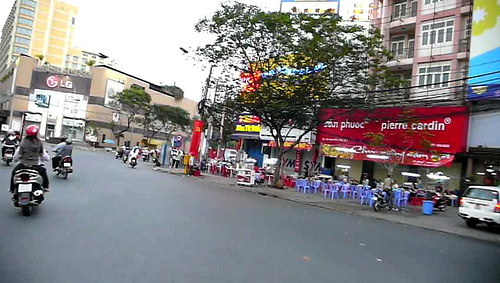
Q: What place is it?
A: It is a road.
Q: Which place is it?
A: It is a road.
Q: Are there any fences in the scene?
A: No, there are no fences.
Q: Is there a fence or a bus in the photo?
A: No, there are no fences or buses.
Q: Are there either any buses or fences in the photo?
A: No, there are no fences or buses.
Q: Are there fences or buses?
A: No, there are no fences or buses.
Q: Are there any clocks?
A: No, there are no clocks.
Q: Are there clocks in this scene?
A: No, there are no clocks.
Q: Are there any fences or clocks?
A: No, there are no clocks or fences.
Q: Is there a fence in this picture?
A: No, there are no fences.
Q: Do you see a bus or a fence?
A: No, there are no fences or buses.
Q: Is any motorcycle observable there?
A: Yes, there is a motorcycle.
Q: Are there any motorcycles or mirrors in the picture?
A: Yes, there is a motorcycle.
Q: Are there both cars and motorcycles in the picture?
A: Yes, there are both a motorcycle and a car.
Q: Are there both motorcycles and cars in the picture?
A: Yes, there are both a motorcycle and a car.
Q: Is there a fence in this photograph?
A: No, there are no fences.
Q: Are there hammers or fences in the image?
A: No, there are no fences or hammers.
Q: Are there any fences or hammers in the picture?
A: No, there are no fences or hammers.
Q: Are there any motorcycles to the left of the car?
A: Yes, there is a motorcycle to the left of the car.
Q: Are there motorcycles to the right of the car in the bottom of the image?
A: No, the motorcycle is to the left of the car.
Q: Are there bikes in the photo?
A: Yes, there is a bike.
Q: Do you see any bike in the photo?
A: Yes, there is a bike.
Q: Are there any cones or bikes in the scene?
A: Yes, there is a bike.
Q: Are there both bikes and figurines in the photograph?
A: No, there is a bike but no figurines.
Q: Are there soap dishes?
A: No, there are no soap dishes.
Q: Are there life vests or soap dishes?
A: No, there are no soap dishes or life vests.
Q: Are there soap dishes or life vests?
A: No, there are no soap dishes or life vests.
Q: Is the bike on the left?
A: Yes, the bike is on the left of the image.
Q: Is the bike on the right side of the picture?
A: No, the bike is on the left of the image.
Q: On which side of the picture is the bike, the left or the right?
A: The bike is on the left of the image.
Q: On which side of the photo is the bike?
A: The bike is on the left of the image.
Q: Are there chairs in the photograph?
A: Yes, there is a chair.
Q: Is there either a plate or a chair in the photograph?
A: Yes, there is a chair.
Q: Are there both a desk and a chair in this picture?
A: No, there is a chair but no desks.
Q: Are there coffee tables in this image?
A: No, there are no coffee tables.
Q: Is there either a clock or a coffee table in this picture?
A: No, there are no coffee tables or clocks.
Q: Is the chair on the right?
A: Yes, the chair is on the right of the image.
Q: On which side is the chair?
A: The chair is on the right of the image.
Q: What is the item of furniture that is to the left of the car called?
A: The piece of furniture is a chair.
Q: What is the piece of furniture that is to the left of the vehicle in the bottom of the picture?
A: The piece of furniture is a chair.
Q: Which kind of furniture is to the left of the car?
A: The piece of furniture is a chair.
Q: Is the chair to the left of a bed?
A: No, the chair is to the left of the car.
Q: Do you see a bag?
A: No, there are no bags.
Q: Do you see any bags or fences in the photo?
A: No, there are no bags or fences.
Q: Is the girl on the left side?
A: Yes, the girl is on the left of the image.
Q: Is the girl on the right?
A: No, the girl is on the left of the image.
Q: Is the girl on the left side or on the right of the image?
A: The girl is on the left of the image.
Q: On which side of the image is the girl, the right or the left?
A: The girl is on the left of the image.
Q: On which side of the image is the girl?
A: The girl is on the left of the image.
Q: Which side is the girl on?
A: The girl is on the left of the image.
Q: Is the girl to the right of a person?
A: No, the girl is to the left of a person.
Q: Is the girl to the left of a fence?
A: No, the girl is to the left of a person.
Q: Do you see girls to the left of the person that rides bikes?
A: Yes, there is a girl to the left of the person.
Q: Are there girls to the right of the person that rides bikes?
A: No, the girl is to the left of the person.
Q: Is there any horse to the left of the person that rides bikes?
A: No, there is a girl to the left of the person.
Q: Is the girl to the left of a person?
A: Yes, the girl is to the left of a person.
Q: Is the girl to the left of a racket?
A: No, the girl is to the left of a person.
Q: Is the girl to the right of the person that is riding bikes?
A: No, the girl is to the left of the person.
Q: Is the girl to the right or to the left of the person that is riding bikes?
A: The girl is to the left of the person.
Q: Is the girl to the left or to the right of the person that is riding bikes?
A: The girl is to the left of the person.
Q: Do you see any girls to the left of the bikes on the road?
A: Yes, there is a girl to the left of the bikes.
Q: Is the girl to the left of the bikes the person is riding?
A: Yes, the girl is to the left of the bikes.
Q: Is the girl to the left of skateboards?
A: No, the girl is to the left of the bikes.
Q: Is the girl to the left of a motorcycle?
A: Yes, the girl is to the left of a motorcycle.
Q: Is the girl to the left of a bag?
A: No, the girl is to the left of a motorcycle.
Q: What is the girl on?
A: The girl is on the bike.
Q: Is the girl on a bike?
A: Yes, the girl is on a bike.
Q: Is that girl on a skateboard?
A: No, the girl is on a bike.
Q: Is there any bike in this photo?
A: Yes, there are bikes.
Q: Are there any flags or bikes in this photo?
A: Yes, there are bikes.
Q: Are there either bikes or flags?
A: Yes, there are bikes.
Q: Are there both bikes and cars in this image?
A: Yes, there are both bikes and a car.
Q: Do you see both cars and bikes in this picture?
A: Yes, there are both bikes and a car.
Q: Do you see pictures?
A: No, there are no pictures.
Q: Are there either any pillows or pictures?
A: No, there are no pictures or pillows.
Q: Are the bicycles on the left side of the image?
A: Yes, the bicycles are on the left of the image.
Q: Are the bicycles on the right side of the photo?
A: No, the bicycles are on the left of the image.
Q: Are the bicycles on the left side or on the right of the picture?
A: The bicycles are on the left of the image.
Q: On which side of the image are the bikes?
A: The bikes are on the left of the image.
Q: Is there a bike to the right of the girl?
A: Yes, there are bikes to the right of the girl.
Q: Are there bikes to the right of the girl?
A: Yes, there are bikes to the right of the girl.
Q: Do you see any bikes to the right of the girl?
A: Yes, there are bikes to the right of the girl.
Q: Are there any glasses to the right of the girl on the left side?
A: No, there are bikes to the right of the girl.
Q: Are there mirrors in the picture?
A: No, there are no mirrors.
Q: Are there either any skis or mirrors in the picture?
A: No, there are no mirrors or skis.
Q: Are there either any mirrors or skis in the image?
A: No, there are no mirrors or skis.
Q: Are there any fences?
A: No, there are no fences.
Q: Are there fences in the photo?
A: No, there are no fences.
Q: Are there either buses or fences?
A: No, there are no fences or buses.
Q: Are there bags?
A: No, there are no bags.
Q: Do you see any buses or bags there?
A: No, there are no bags or buses.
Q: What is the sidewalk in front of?
A: The sidewalk is in front of the building.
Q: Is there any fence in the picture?
A: No, there are no fences.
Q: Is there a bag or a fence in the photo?
A: No, there are no fences or bags.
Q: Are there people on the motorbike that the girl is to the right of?
A: Yes, there is a person on the motorbike.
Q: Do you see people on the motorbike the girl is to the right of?
A: Yes, there is a person on the motorbike.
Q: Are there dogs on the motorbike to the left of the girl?
A: No, there is a person on the motorbike.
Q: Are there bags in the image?
A: No, there are no bags.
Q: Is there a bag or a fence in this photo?
A: No, there are no bags or fences.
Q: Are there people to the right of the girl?
A: Yes, there is a person to the right of the girl.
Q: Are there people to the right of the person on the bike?
A: Yes, there is a person to the right of the girl.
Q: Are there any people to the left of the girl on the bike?
A: No, the person is to the right of the girl.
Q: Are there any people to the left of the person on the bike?
A: No, the person is to the right of the girl.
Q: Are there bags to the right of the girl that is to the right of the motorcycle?
A: No, there is a person to the right of the girl.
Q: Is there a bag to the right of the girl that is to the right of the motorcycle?
A: No, there is a person to the right of the girl.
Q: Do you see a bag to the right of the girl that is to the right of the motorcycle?
A: No, there is a person to the right of the girl.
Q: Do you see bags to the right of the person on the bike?
A: No, there is a person to the right of the girl.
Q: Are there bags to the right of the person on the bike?
A: No, there is a person to the right of the girl.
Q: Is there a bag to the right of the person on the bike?
A: No, there is a person to the right of the girl.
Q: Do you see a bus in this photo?
A: No, there are no buses.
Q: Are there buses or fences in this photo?
A: No, there are no buses or fences.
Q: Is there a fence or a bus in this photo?
A: No, there are no buses or fences.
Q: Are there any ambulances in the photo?
A: No, there are no ambulances.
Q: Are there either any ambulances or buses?
A: No, there are no ambulances or buses.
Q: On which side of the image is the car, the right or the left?
A: The car is on the right of the image.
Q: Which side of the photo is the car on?
A: The car is on the right of the image.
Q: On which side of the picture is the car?
A: The car is on the right of the image.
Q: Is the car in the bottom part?
A: Yes, the car is in the bottom of the image.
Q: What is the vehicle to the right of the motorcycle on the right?
A: The vehicle is a car.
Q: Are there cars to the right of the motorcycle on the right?
A: Yes, there is a car to the right of the motorbike.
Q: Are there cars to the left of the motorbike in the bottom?
A: No, the car is to the right of the motorcycle.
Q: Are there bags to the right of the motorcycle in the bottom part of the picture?
A: No, there is a car to the right of the motorbike.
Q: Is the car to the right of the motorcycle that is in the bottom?
A: Yes, the car is to the right of the motorcycle.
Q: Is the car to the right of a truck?
A: No, the car is to the right of the motorcycle.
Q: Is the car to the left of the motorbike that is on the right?
A: No, the car is to the right of the motorcycle.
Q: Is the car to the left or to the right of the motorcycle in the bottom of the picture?
A: The car is to the right of the motorcycle.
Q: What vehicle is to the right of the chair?
A: The vehicle is a car.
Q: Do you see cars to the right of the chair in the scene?
A: Yes, there is a car to the right of the chair.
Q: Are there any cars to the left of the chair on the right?
A: No, the car is to the right of the chair.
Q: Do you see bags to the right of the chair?
A: No, there is a car to the right of the chair.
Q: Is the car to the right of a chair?
A: Yes, the car is to the right of a chair.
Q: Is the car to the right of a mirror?
A: No, the car is to the right of a chair.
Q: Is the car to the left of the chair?
A: No, the car is to the right of the chair.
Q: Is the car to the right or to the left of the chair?
A: The car is to the right of the chair.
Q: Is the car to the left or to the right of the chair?
A: The car is to the right of the chair.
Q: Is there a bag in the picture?
A: No, there are no bags.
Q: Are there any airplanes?
A: No, there are no airplanes.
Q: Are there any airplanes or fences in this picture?
A: No, there are no airplanes or fences.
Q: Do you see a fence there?
A: No, there are no fences.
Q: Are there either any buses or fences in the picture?
A: No, there are no fences or buses.